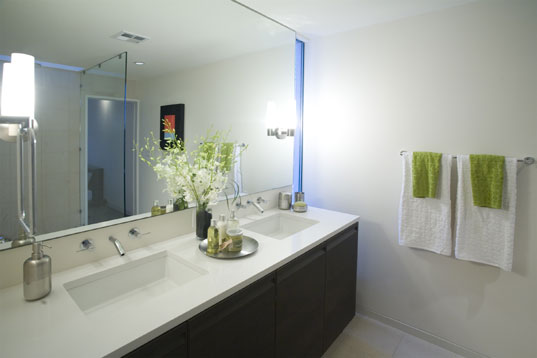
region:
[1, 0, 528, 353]
Spacious bathroom vanity, showing Toiletries, towels, decorative items and flowers.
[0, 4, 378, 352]
Large, bathroom vanity.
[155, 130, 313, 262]
Sink, beside toiletries, tray and flowers.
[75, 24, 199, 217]
Glass door, door frame and picure, reflected in vanity mirror.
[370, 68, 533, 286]
Metal bar with green wash cloths and white towels.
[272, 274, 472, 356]
Corner,showing brown cabinets,white floor and wall.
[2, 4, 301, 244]
Large, glass mirror,dominating room.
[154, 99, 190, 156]
picture hanging on the wall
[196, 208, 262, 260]
a group of bottles on a plate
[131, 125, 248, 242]
green and white flowers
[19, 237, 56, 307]
a bottle sitting by the sink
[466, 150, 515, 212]
a green towel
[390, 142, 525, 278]
green and white towels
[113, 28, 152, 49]
a vent on the ceiling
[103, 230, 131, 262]
a sink faucet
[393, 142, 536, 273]
towels hanging on a rack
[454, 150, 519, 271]
white bathroom body towel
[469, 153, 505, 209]
small green hand towel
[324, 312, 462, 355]
white tile bathroom floor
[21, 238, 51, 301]
large silver soap dispenser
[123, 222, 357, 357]
dark brown wooden counter drawers and doors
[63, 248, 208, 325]
square inset bathroom sink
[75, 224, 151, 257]
simple wall mounted sink faucet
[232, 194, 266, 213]
simple wall mounted sink faucet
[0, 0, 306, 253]
large wall mounted bathroom mirror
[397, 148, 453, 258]
small green towel on top of large white towel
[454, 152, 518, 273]
small green towel on top of large white towel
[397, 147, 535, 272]
four towels hanging on a towel rack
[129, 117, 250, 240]
white and green flowers in a black vase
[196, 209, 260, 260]
silver tray with several bottles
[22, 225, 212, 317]
silver soap dispenser next to sink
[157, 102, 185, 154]
red and blue artwork inside a black frame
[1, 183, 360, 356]
two-sink vanity with brown doors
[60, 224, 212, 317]
sink with silver faucets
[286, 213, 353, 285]
A person eating a orange.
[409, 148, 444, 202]
a hanging green towel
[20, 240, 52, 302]
a silver soap dispenser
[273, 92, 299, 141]
a silver metal light fixture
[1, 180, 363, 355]
a wooden and white sink cabinet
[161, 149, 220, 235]
flower arrangement on the sink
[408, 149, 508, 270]
white and green towels on the rack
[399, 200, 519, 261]
bottom of the white towels on the rack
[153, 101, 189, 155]
the reflection of the artwork in the mirror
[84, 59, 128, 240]
the clear glass shower wall in the mirror's reflection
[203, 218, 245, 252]
the accessories between the two sinks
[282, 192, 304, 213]
the canisters in the corner of the sink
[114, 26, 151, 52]
the bathroom vent on the ceiling.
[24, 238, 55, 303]
a soap dispenser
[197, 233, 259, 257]
a round silver tray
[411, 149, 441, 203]
a small green towel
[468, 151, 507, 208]
a small green towel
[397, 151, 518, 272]
two large white towels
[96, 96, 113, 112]
a light reflected in the mirror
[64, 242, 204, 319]
a white rectangular sink bowl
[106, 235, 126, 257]
a silver water faucet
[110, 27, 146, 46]
a vent reflected in the mirror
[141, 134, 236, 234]
the flowers are in the vase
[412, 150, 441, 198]
the towel is green and hanging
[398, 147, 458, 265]
the white towel is on the rack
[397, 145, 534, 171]
towel rack on the wall